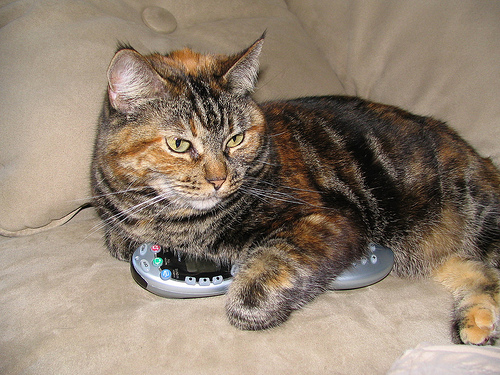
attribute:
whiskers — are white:
[116, 180, 298, 226]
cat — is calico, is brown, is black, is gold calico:
[71, 27, 498, 346]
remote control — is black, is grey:
[129, 226, 401, 298]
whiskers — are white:
[72, 167, 170, 227]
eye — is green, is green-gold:
[161, 130, 196, 153]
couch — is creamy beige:
[14, 20, 425, 336]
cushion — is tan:
[285, 0, 498, 154]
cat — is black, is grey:
[283, 110, 445, 215]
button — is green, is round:
[151, 256, 165, 267]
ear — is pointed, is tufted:
[97, 39, 173, 100]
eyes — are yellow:
[162, 121, 249, 155]